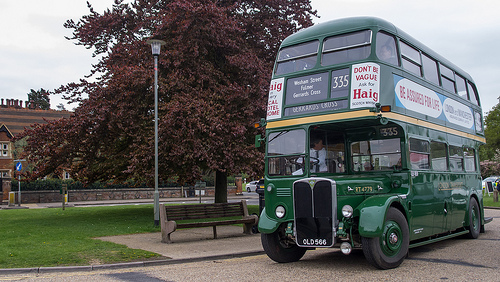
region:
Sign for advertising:
[346, 56, 385, 113]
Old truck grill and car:
[259, 150, 400, 266]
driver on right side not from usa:
[270, 135, 337, 180]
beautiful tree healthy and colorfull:
[172, 25, 244, 176]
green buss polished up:
[342, 138, 482, 265]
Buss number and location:
[277, 65, 348, 118]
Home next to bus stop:
[0, 101, 87, 216]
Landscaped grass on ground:
[1, 211, 131, 265]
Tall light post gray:
[149, 30, 162, 232]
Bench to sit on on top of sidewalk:
[160, 188, 250, 245]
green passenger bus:
[250, 16, 470, 279]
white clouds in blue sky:
[0, 1, 44, 27]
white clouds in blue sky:
[19, 36, 60, 64]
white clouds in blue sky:
[9, 20, 47, 72]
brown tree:
[190, 44, 223, 78]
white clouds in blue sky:
[433, 12, 474, 42]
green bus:
[281, 22, 481, 242]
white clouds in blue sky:
[444, 19, 478, 61]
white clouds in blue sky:
[55, 51, 94, 92]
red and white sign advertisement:
[350, 65, 383, 107]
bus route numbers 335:
[330, 70, 352, 98]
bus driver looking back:
[291, 131, 328, 174]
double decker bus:
[251, 14, 496, 267]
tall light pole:
[143, 37, 164, 217]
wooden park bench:
[155, 201, 260, 241]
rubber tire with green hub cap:
[361, 207, 417, 269]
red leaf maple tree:
[18, 2, 310, 203]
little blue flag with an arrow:
[11, 156, 21, 167]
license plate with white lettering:
[295, 236, 330, 248]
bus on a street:
[237, 16, 492, 264]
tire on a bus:
[360, 191, 415, 272]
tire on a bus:
[465, 190, 487, 238]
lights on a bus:
[340, 200, 356, 258]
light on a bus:
[265, 200, 288, 221]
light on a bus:
[260, 177, 281, 198]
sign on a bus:
[350, 50, 380, 103]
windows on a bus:
[316, 25, 376, 60]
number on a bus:
[370, 122, 417, 142]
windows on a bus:
[268, 35, 317, 76]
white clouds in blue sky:
[4, 11, 51, 42]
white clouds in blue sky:
[27, 39, 76, 80]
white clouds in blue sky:
[403, 0, 469, 46]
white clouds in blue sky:
[427, 17, 463, 55]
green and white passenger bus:
[281, 22, 461, 269]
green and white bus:
[260, 24, 482, 247]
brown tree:
[131, 66, 221, 123]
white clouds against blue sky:
[11, 8, 57, 65]